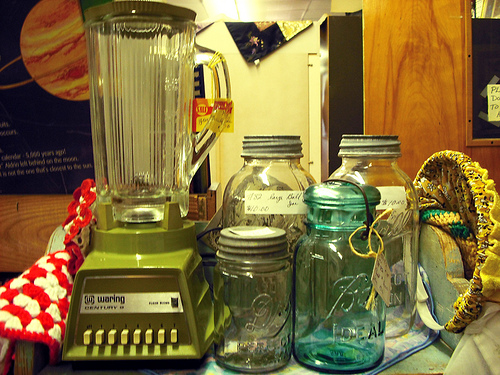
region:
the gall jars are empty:
[232, 213, 367, 373]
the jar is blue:
[314, 190, 392, 374]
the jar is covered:
[300, 186, 395, 373]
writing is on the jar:
[321, 273, 398, 355]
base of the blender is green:
[72, 225, 234, 372]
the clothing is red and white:
[24, 236, 70, 351]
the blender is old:
[83, 58, 225, 372]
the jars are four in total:
[207, 126, 422, 367]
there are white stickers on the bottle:
[235, 187, 307, 226]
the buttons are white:
[76, 324, 193, 351]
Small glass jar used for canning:
[211, 227, 295, 374]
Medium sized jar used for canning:
[295, 171, 386, 372]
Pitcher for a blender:
[75, 0, 225, 215]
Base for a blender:
[62, 211, 209, 366]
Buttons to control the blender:
[76, 320, 176, 345]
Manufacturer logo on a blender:
[80, 293, 131, 314]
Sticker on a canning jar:
[242, 182, 314, 215]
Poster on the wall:
[0, 10, 111, 197]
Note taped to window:
[484, 80, 499, 130]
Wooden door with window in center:
[362, 0, 499, 172]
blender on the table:
[81, 19, 223, 216]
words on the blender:
[76, 278, 185, 329]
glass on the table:
[210, 223, 300, 348]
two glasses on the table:
[227, 188, 390, 343]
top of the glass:
[294, 168, 381, 225]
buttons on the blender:
[73, 319, 183, 358]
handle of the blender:
[196, 41, 276, 138]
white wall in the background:
[243, 69, 297, 118]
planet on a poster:
[17, 14, 69, 111]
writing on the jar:
[251, 179, 299, 219]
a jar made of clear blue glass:
[303, 185, 380, 361]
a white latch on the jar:
[352, 180, 364, 193]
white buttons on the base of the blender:
[77, 326, 197, 353]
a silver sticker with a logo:
[87, 292, 179, 311]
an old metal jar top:
[219, 224, 300, 265]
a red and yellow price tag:
[194, 97, 231, 124]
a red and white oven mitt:
[9, 271, 62, 336]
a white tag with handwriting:
[374, 252, 393, 301]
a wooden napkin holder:
[429, 236, 460, 293]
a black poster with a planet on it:
[6, 9, 84, 175]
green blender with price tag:
[50, 11, 233, 366]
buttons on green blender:
[75, 319, 183, 351]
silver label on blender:
[78, 283, 191, 323]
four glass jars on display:
[213, 128, 425, 372]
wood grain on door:
[390, 8, 455, 114]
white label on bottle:
[235, 179, 307, 219]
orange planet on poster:
[23, 11, 85, 105]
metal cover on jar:
[234, 130, 314, 165]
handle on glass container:
[184, 41, 234, 168]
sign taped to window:
[477, 71, 499, 126]